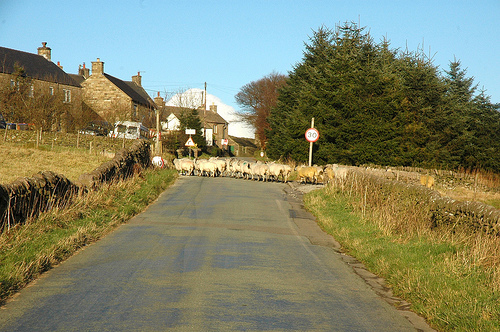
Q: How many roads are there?
A: One.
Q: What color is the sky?
A: Blue.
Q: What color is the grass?
A: Green and yellow.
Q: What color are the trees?
A: Green.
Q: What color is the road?
A: Gray.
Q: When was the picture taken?
A: Daytime.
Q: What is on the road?
A: Sheep.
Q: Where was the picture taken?
A: On a country road.